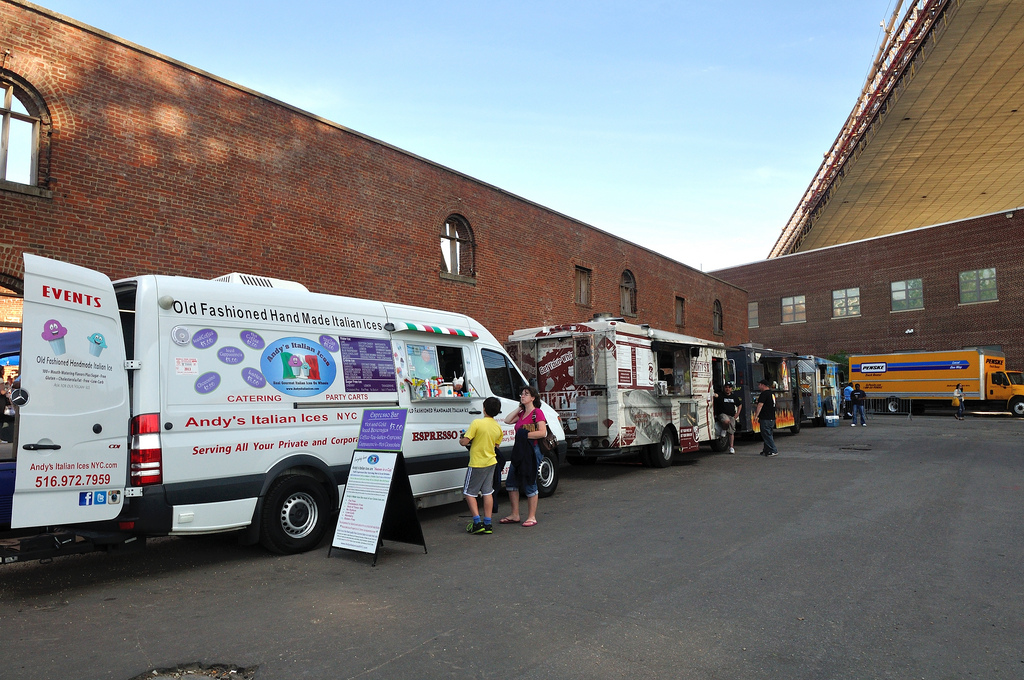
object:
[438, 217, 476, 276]
window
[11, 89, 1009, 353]
building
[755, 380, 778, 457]
boy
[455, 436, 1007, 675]
drive way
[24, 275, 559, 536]
truck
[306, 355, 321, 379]
flames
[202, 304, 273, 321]
word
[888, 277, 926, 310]
window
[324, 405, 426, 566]
board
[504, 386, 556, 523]
people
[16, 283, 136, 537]
door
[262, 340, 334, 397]
ices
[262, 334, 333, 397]
faces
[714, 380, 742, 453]
person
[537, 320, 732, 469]
truck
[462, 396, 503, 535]
boy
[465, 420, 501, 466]
shirt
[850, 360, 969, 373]
stripe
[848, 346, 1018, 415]
truck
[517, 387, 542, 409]
hair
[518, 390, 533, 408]
face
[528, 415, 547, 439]
arm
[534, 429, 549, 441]
elbow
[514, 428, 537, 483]
jacket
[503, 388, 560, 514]
woman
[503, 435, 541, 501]
pants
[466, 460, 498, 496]
shorts